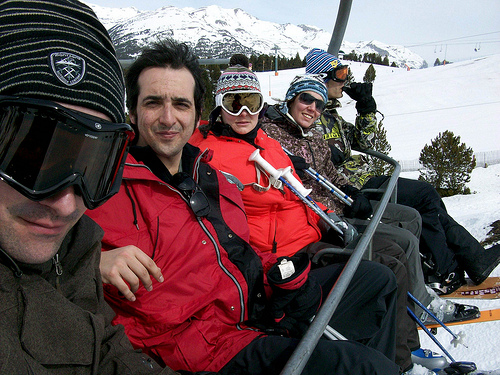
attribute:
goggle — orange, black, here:
[2, 77, 137, 221]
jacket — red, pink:
[117, 149, 267, 347]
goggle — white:
[215, 93, 299, 137]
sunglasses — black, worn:
[291, 84, 334, 115]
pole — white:
[253, 152, 335, 213]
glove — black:
[346, 77, 389, 123]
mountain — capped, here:
[160, 10, 304, 67]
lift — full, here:
[247, 44, 291, 66]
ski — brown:
[433, 276, 482, 339]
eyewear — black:
[295, 87, 359, 116]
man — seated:
[162, 45, 304, 366]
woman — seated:
[275, 68, 379, 257]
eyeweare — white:
[220, 84, 274, 124]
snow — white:
[399, 74, 475, 143]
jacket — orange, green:
[258, 127, 350, 204]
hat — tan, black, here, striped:
[16, 9, 121, 125]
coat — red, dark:
[212, 120, 335, 302]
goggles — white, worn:
[325, 65, 374, 76]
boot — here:
[459, 230, 499, 304]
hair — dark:
[128, 33, 209, 104]